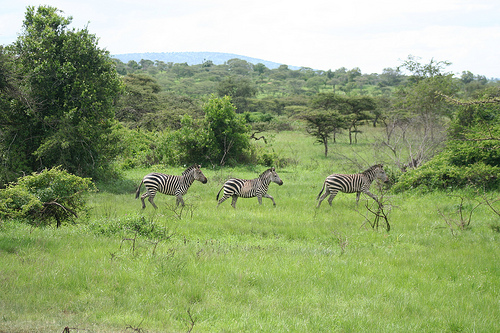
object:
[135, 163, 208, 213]
zebra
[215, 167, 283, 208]
zebra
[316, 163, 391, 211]
zebra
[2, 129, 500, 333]
grass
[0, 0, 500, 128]
forest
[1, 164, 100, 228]
bush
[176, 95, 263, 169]
bush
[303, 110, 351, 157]
tree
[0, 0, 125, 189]
tree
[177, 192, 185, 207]
front leg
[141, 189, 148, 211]
back leg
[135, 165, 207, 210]
mane